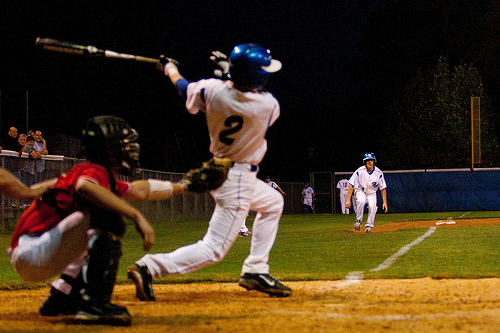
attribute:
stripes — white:
[351, 220, 441, 276]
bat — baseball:
[25, 26, 180, 77]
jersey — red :
[17, 162, 127, 246]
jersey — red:
[9, 155, 134, 251]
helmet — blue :
[226, 45, 281, 78]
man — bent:
[345, 152, 391, 235]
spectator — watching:
[35, 136, 50, 145]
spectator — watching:
[3, 117, 17, 131]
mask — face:
[87, 124, 157, 169]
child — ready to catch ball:
[10, 126, 234, 323]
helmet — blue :
[232, 47, 277, 69]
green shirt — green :
[22, 142, 39, 155]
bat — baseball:
[36, 32, 160, 64]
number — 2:
[217, 110, 243, 147]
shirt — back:
[166, 73, 281, 164]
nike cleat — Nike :
[236, 267, 293, 297]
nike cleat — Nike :
[123, 264, 157, 304]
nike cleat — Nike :
[72, 300, 131, 323]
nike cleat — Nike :
[38, 289, 78, 319]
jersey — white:
[182, 78, 283, 165]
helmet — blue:
[229, 42, 285, 89]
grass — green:
[408, 219, 489, 262]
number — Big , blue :
[215, 111, 245, 147]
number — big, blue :
[216, 110, 244, 149]